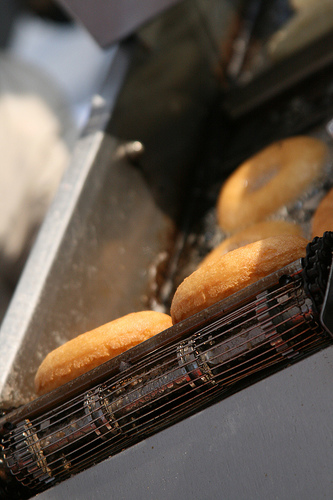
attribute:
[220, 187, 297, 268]
doughnut — fried, frying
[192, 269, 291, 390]
gear — metal, turning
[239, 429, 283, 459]
wall — silver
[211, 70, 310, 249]
fryer — hot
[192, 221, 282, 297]
donut — cooked, going, un-glazed, moving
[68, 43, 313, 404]
machine — turning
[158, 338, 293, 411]
wire — metal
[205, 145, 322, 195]
light — crusted